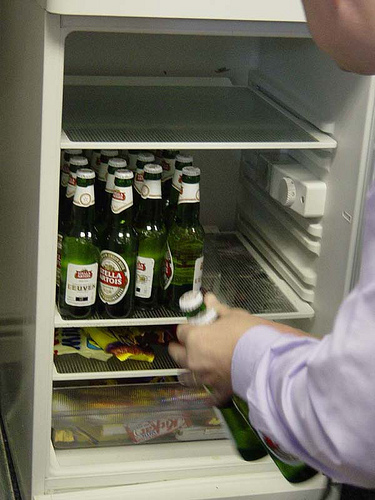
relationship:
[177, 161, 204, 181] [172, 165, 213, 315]
cap on bottle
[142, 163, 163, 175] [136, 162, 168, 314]
cap on bottle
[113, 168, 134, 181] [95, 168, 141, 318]
cap on bottle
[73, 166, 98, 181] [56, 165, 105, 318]
cap on bottle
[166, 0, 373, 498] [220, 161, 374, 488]
man wearing shirt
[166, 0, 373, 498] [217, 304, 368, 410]
man wearing shirt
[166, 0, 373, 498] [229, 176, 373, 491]
man wearing shirt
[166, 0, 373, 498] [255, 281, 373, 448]
man wearing shirt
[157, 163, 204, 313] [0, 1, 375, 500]
bottle in fridge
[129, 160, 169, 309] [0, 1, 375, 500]
bottle in fridge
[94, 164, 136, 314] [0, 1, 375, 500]
bottle in fridge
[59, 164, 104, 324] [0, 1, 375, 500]
bottle in fridge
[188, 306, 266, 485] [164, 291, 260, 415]
beer in hand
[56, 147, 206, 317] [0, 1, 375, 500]
beer in fridge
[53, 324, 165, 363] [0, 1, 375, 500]
food in fridge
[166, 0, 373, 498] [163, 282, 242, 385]
man holding bottles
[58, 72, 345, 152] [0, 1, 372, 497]
shelf in fridge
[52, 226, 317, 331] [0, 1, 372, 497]
shelf in fridge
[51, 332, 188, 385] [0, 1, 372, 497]
shelf in fridge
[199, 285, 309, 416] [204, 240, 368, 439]
cufflink on shirt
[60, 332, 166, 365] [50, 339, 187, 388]
food on shelf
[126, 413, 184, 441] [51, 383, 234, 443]
kitkat bar in drawer